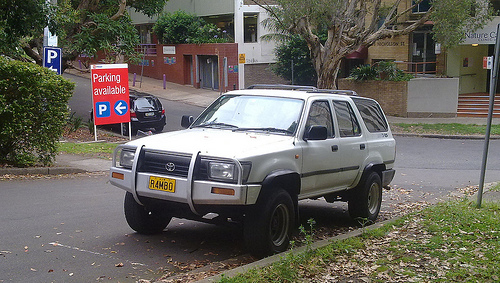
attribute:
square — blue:
[44, 46, 63, 76]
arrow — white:
[113, 100, 129, 116]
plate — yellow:
[145, 169, 182, 196]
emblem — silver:
[157, 163, 188, 179]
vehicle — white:
[111, 85, 413, 232]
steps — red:
[452, 92, 500, 126]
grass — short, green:
[375, 191, 500, 268]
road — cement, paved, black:
[35, 178, 79, 261]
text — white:
[95, 69, 134, 96]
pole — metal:
[475, 72, 492, 224]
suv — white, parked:
[116, 75, 403, 202]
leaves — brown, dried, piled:
[332, 204, 465, 273]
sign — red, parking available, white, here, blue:
[91, 66, 125, 135]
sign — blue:
[39, 44, 65, 81]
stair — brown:
[471, 92, 499, 117]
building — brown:
[370, 4, 489, 115]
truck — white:
[92, 83, 422, 240]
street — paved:
[31, 177, 154, 278]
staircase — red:
[445, 73, 496, 116]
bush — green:
[0, 50, 69, 161]